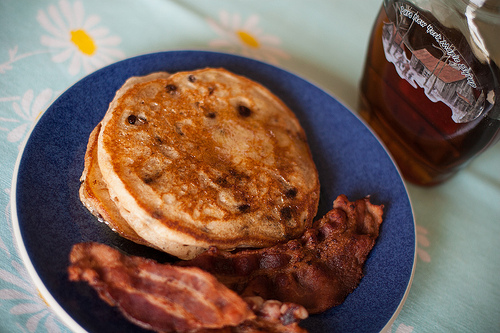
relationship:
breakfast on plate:
[10, 50, 417, 332] [0, 42, 422, 331]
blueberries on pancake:
[157, 74, 257, 124] [75, 67, 322, 257]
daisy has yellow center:
[32, 4, 132, 74] [188, 118, 240, 164]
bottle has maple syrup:
[350, 5, 499, 201] [358, 0, 500, 188]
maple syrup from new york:
[358, 0, 500, 188] [377, 22, 487, 132]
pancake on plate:
[75, 67, 322, 257] [0, 42, 422, 331]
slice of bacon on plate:
[61, 240, 312, 332] [0, 42, 422, 331]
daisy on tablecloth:
[32, 0, 132, 74] [15, 5, 485, 273]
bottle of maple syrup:
[350, 0, 498, 189] [358, 0, 500, 188]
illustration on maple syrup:
[378, 12, 482, 112] [358, 0, 500, 188]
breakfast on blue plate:
[62, 62, 392, 332] [0, 0, 498, 332]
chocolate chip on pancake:
[235, 104, 251, 117] [86, 67, 357, 255]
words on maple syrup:
[392, 1, 482, 74] [358, 0, 500, 188]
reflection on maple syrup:
[448, 2, 485, 32] [358, 0, 500, 188]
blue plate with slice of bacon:
[38, 49, 404, 330] [61, 240, 312, 332]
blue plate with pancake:
[16, 49, 416, 333] [75, 67, 322, 257]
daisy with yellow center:
[32, 0, 132, 74] [58, 20, 113, 59]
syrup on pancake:
[368, 2, 483, 138] [75, 67, 322, 257]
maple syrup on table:
[358, 0, 500, 188] [11, 6, 474, 135]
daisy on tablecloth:
[32, 0, 132, 74] [7, 11, 421, 295]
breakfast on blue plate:
[62, 62, 392, 332] [7, 50, 418, 331]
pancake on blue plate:
[75, 67, 322, 257] [16, 49, 416, 333]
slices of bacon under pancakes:
[57, 195, 383, 333] [100, 59, 349, 281]